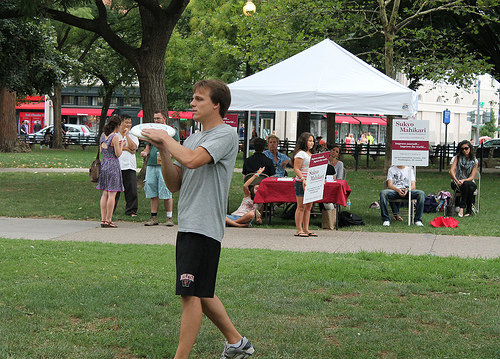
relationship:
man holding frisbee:
[132, 77, 258, 350] [131, 121, 178, 145]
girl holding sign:
[284, 124, 326, 239] [302, 150, 334, 225]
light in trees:
[242, 1, 253, 14] [4, 1, 499, 105]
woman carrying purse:
[447, 138, 482, 221] [95, 151, 100, 177]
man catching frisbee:
[132, 77, 258, 350] [131, 121, 178, 145]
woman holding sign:
[447, 138, 482, 221] [302, 150, 334, 225]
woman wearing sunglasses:
[447, 138, 482, 221] [459, 143, 470, 152]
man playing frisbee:
[132, 77, 258, 350] [131, 121, 178, 145]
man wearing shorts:
[132, 77, 258, 350] [171, 226, 231, 300]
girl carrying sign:
[284, 124, 326, 239] [302, 150, 334, 225]